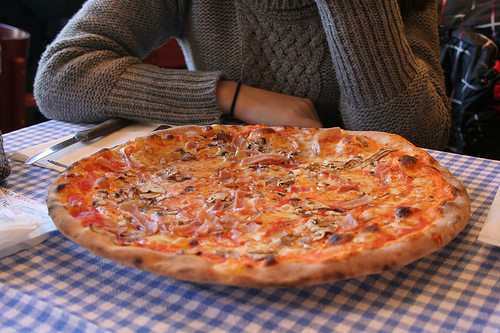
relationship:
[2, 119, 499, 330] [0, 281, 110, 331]
table cloth has wrinkle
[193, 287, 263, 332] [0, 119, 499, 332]
lines are printed on table cloth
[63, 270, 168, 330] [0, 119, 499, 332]
lines are printed on table cloth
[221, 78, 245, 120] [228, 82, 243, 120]
tie attached to tie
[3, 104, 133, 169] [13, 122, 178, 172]
knife on top of paper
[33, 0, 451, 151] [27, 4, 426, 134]
person wearing sweater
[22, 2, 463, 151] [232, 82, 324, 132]
person has hand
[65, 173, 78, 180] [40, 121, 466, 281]
dark spot on pizza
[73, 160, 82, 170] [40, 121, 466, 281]
dark spot on pizza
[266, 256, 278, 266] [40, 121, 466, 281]
dark spot on pizza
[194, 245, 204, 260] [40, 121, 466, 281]
dark spot on pizza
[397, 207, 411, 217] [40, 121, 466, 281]
dark spot on pizza